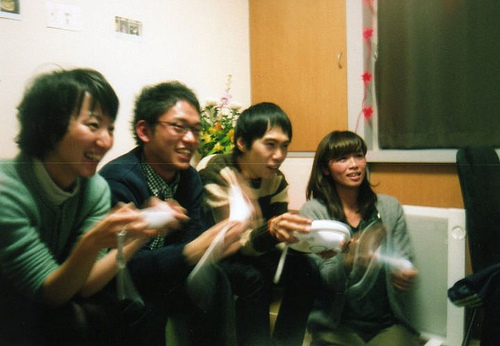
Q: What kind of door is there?
A: Brown wooden.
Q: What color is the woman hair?
A: Black.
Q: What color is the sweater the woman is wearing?
A: Gray.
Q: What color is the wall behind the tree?
A: White.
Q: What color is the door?
A: Brown.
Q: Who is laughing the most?
A: The woman with short hair.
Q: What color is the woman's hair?
A: Black.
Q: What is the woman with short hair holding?
A: A Wii.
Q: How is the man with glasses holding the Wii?
A: Like a steering wheel.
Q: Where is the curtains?
A: Over the window.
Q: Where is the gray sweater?
A: On the woman.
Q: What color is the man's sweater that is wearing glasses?
A: Blue.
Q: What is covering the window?
A: A shade.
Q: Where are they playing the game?
A: In the living room.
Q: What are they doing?
A: Playing a video game.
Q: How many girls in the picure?
A: Two.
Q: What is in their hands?
A: Game controllers.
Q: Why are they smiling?
A: They are having fun.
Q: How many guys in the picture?
A: Two.